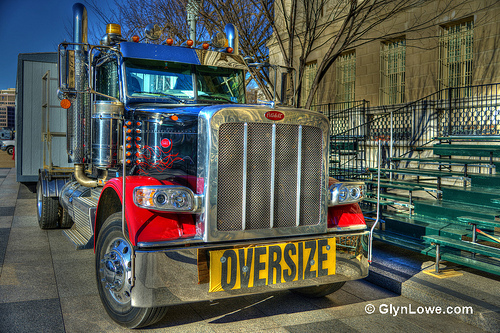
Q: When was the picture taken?
A: Daytime.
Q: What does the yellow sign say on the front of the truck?
A: Oversize.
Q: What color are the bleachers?
A: Green.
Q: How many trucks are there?
A: One.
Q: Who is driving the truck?
A: Truck driver.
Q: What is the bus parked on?
A: Sidewalk.